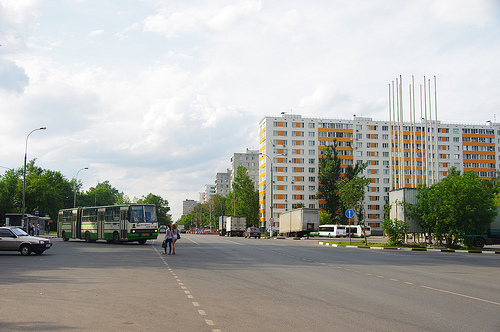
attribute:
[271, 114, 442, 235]
building — white and orange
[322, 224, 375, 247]
buses — two and white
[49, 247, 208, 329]
road — edge